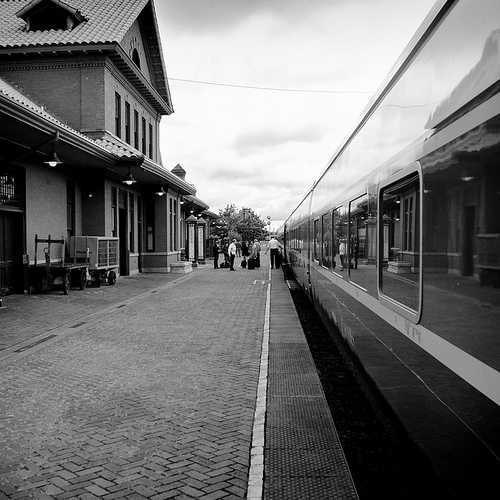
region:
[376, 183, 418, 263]
window of a train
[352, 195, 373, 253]
window of a train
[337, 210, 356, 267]
window of a train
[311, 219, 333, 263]
window of a train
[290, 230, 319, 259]
window of a train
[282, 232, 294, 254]
window of a train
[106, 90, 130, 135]
window of a building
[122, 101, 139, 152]
window of a building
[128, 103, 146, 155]
window of a building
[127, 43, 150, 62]
window of a building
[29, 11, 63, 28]
window of a building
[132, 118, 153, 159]
window of a building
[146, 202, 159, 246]
window of a building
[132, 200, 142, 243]
window of a building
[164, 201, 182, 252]
window of a building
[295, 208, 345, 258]
window of a train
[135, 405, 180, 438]
the road is paved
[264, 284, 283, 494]
white line on road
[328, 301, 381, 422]
hole in the platform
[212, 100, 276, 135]
clouds in the sky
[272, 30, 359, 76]
the weather is overcast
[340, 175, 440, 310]
pole on the platform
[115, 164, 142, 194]
light under the awning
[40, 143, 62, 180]
light under the awning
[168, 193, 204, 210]
light under the awning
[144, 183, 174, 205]
light under the awning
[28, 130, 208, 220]
Lights hanging from building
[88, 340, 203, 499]
Brick sidewalk near train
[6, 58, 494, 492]
Photo is black and white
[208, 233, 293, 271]
People entering train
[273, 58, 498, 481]
Train ready to depart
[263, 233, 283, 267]
Man putting luggage on train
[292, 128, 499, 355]
Building reflective off train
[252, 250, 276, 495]
White line holds guests back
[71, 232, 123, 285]
White cart near building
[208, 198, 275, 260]
Trees in the background near people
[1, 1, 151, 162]
Spanish tiles on the roof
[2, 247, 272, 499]
Platform is made of bricks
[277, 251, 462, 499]
Large gap between the platform and the train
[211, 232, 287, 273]
People either getting on or off the train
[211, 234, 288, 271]
People gathered in a group with luggage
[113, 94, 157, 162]
Five windows on the second floor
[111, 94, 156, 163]
A row of five windows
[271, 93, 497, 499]
The train is highly reflective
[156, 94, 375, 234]
Lots of clouds in the sky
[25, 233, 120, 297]
Two carts sitting near the building